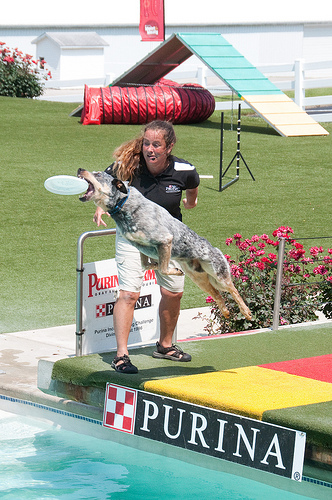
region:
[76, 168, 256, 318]
A dog leaping in the air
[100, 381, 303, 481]
A sign advertising Purina brand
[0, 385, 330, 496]
A swimming pool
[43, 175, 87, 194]
A white frisbee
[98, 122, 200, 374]
A animal trainer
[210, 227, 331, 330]
A flower bed with red flowers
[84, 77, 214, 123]
A large hallow plastic tube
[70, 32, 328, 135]
A steep training ramp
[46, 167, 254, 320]
A dog catching a Frisbee in it's mouth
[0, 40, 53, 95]
A large bush with red flowers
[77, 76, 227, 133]
red dog tunnel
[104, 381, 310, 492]
PURINA sign in front of pool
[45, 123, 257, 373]
woman giving dog directions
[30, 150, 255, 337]
dog jumping for frisbee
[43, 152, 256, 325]
dog jumping for white frisbee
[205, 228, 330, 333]
red and pink roses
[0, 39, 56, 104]
roses in front of building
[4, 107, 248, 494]
dog jumping for frisbee over water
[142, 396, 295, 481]
white letters on black sign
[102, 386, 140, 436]
red and white purina logo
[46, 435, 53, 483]
This is a pool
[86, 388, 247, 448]
The sign says purina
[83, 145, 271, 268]
This is a dog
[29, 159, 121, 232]
This is the frisbee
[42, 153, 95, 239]
The frisbee is white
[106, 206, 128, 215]
This is a collar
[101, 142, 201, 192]
This is a woman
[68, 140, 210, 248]
The dog is jumping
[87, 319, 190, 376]
These are black sandals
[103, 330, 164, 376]
The sandals are black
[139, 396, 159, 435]
the white letter P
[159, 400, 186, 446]
the white letter U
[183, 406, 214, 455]
the white letter R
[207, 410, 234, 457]
the white letter I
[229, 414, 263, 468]
the white letter N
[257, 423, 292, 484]
the white letter A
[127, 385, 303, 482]
the white word Purina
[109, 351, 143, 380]
this is a sandle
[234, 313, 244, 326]
these are the leaves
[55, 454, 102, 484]
this is the water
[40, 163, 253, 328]
dog jumping to catch frisbee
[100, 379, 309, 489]
black and red sign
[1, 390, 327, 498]
small portion of swimming pool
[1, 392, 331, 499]
row of blue decorative tiles on pool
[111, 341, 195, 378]
black leather ladies sandals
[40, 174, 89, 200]
white frisbee in mid-flight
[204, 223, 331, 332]
red flower bush near fence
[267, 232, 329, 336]
silver metal fence enclosure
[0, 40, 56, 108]
red flowered bush in distance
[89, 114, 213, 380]
blonde lady standing near dog